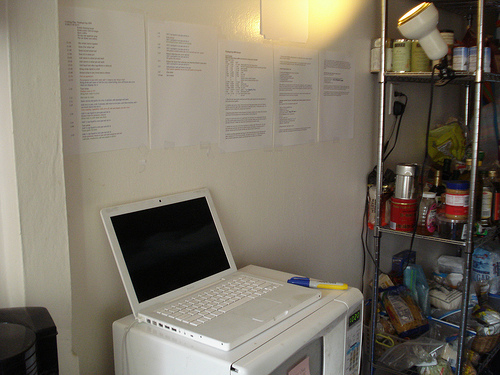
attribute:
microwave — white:
[111, 264, 364, 374]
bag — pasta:
[376, 282, 431, 338]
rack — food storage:
[364, 0, 499, 373]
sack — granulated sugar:
[473, 248, 499, 297]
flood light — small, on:
[393, 2, 451, 63]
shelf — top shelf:
[382, 70, 498, 83]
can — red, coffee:
[391, 194, 413, 233]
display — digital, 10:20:
[346, 310, 361, 327]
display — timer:
[347, 309, 361, 329]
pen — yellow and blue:
[289, 276, 349, 291]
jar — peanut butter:
[442, 179, 470, 215]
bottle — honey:
[419, 191, 439, 234]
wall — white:
[2, 1, 454, 371]